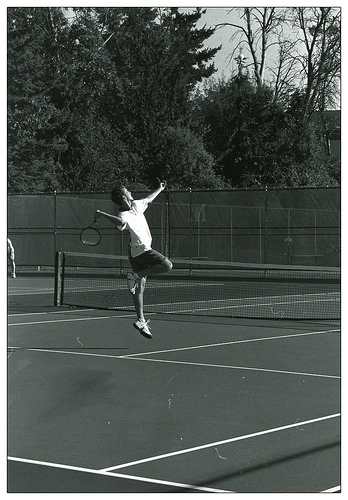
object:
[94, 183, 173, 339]
man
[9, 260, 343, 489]
court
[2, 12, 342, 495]
camera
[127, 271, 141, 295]
shoe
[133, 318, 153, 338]
shoe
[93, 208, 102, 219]
hand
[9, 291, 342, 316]
lines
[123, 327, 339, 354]
lines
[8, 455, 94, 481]
lines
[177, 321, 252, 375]
tennis court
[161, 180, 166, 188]
ball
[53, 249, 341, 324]
dividing net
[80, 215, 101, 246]
racket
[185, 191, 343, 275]
fencing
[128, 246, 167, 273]
shorts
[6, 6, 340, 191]
trees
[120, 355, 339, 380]
lines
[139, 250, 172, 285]
leg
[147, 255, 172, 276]
leg bent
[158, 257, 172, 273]
knee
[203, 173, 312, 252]
tarp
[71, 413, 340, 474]
lines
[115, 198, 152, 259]
shirt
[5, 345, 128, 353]
shadow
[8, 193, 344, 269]
fenceline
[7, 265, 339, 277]
perimeter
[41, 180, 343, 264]
back ground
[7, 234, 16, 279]
person